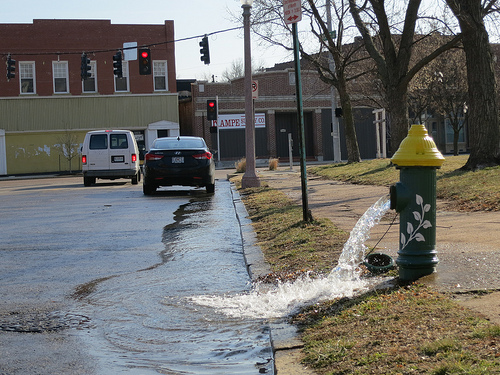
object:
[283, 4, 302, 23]
sign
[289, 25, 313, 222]
pole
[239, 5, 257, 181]
pole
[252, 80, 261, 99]
sign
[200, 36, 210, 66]
lights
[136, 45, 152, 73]
lights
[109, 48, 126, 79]
lights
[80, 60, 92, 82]
lights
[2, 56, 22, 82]
lights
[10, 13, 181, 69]
wire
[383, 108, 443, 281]
hydrant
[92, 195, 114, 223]
shadow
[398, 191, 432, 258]
flower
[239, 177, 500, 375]
grass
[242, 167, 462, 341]
ground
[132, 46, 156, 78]
light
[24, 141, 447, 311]
land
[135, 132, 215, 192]
back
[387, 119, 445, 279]
fire hydrant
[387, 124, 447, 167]
top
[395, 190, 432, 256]
plant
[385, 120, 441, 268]
hydrant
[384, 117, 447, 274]
hydrant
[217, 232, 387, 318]
water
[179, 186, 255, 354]
road side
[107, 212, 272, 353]
puddle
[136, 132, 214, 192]
car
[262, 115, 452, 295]
sidewalk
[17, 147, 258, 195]
intersection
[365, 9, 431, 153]
tree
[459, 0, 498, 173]
bark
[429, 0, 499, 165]
tree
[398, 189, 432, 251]
design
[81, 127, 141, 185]
van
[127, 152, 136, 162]
brake light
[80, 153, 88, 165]
brake light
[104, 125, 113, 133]
brake light